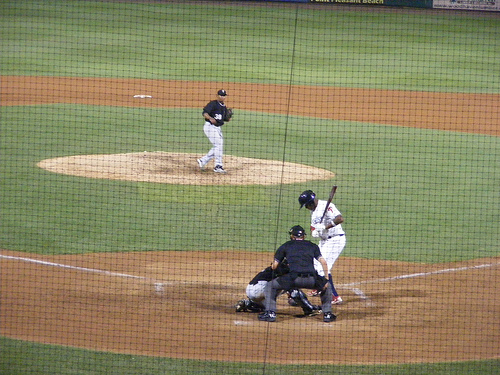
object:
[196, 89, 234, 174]
pitcher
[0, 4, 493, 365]
baseball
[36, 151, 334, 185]
mound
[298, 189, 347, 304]
player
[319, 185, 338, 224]
bat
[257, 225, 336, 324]
umpire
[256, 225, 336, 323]
protection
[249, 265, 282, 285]
catcher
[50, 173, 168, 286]
ground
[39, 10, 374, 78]
astroturf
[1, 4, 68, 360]
netting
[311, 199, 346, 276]
uniform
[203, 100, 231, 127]
black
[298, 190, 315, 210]
helmet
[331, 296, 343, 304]
shoes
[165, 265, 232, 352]
dirt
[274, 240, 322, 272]
shirt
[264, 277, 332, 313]
pants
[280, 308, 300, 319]
home plate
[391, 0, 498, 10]
fence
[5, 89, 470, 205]
center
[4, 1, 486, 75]
outfield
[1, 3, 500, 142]
field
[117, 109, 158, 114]
base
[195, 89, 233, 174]
players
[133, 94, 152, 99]
second base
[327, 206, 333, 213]
stripe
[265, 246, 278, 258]
down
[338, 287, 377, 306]
line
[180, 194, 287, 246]
grass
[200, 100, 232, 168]
uniform